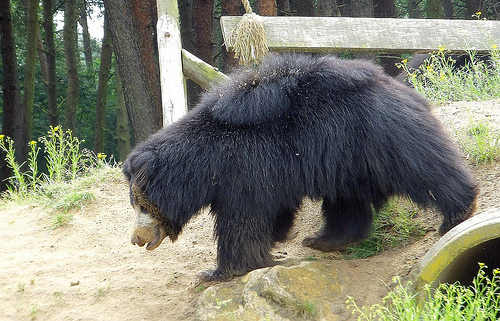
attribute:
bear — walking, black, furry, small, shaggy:
[123, 53, 480, 280]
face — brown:
[122, 154, 183, 249]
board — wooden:
[219, 14, 500, 50]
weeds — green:
[403, 52, 499, 102]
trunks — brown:
[101, 0, 159, 142]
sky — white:
[55, 1, 116, 45]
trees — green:
[10, 9, 119, 144]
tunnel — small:
[418, 205, 499, 296]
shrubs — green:
[460, 121, 499, 163]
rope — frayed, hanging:
[227, 4, 272, 67]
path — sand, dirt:
[6, 98, 492, 316]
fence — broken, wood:
[155, 1, 498, 124]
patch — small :
[61, 189, 96, 212]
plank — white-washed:
[153, 13, 189, 124]